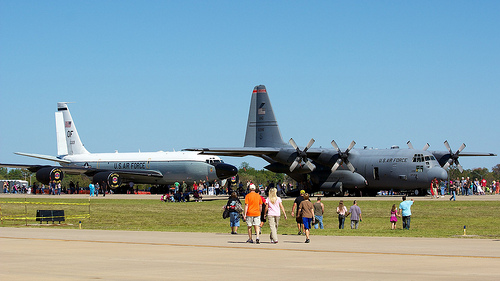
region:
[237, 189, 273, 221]
man wearing orange shirt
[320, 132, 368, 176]
propellers on planes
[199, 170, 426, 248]
people walking on the ground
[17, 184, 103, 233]
thin yellow barrier tapes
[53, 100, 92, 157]
emblem on side of plane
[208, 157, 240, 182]
black nose on plane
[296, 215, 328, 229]
pair of blue shorts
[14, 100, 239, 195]
a large white and silver airplane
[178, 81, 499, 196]
a large grey airplane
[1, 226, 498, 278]
a brown airport tarmac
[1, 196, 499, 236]
a green strip of grass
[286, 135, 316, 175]
a large grey plane propellor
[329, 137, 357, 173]
a large grey plane propellor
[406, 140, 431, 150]
a large grey plane propellor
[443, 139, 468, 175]
a large grey plane propellor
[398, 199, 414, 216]
a light blue t-shirt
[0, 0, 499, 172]
a clear blue sky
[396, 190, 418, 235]
This is a person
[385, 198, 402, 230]
This is a person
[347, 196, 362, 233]
This is a person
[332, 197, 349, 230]
This is a person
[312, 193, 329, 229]
This is a person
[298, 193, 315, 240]
This is a person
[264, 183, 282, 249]
This is a person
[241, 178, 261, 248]
This is a person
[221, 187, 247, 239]
This is a person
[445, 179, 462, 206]
This is a person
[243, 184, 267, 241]
man with an orange tee shirt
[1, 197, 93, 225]
caution tape around a small area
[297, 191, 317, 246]
boy with blue shorts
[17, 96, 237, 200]
white air force plane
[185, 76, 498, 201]
grey air force plane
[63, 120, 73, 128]
flag on a white air force plane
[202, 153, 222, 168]
cockpit on a white air force plane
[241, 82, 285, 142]
tail of a grey air force plane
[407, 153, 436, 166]
cockpit of a grey air force plane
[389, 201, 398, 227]
girl with a pink dress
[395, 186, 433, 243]
this is a person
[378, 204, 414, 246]
this is a person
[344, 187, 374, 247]
this is a person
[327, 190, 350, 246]
this is a person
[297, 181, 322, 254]
this is a person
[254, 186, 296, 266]
this is a person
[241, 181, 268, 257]
this is a person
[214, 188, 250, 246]
this is a person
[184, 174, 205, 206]
this is a person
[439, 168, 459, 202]
this is a person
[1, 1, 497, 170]
blue in daytime sky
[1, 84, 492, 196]
two parked military planes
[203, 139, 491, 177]
propellers on plane wings